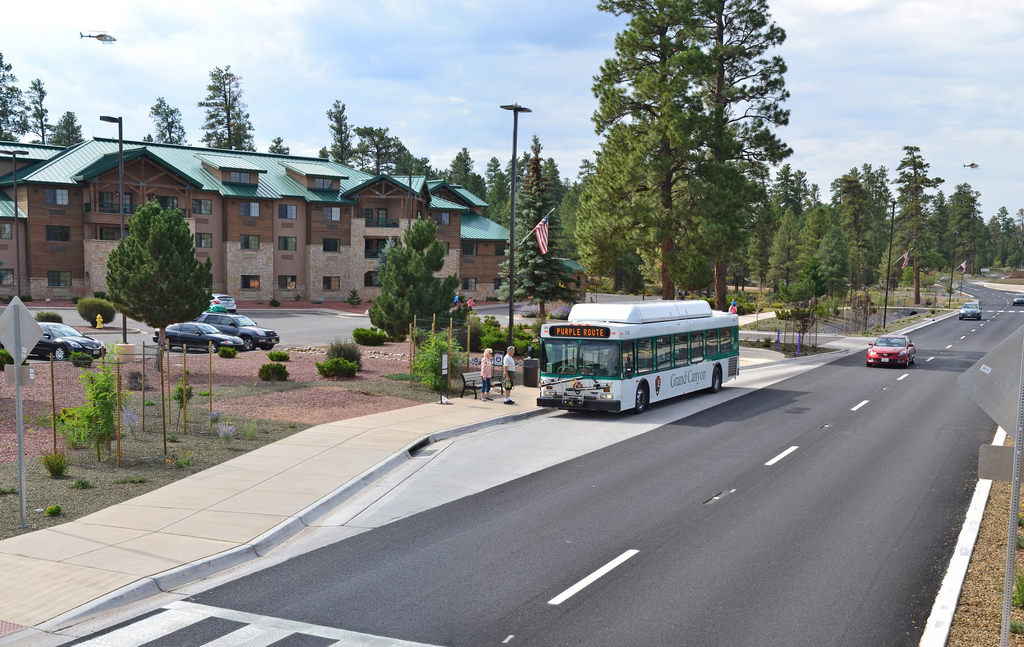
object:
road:
[0, 276, 1024, 647]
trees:
[575, 0, 788, 312]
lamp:
[500, 103, 532, 113]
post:
[509, 111, 514, 346]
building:
[0, 137, 515, 304]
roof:
[0, 137, 512, 240]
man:
[503, 346, 516, 404]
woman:
[480, 348, 493, 402]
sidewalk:
[0, 381, 553, 647]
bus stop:
[537, 299, 739, 414]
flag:
[518, 208, 554, 255]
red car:
[866, 335, 916, 368]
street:
[0, 299, 788, 647]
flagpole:
[518, 208, 554, 246]